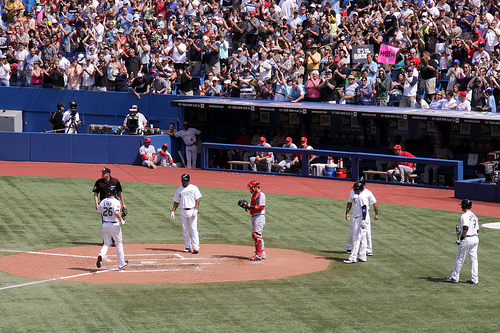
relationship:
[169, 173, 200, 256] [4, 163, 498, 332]
person on top of field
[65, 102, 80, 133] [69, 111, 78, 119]
man taking pictures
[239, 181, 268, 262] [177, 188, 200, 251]
player in uniform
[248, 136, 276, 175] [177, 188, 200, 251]
player in uniform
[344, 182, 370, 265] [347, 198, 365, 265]
player in uniform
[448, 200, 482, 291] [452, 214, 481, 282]
player in uniform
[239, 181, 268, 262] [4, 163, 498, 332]
catcher playing game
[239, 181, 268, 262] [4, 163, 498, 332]
umpire in game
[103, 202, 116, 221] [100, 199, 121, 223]
number on top of jersey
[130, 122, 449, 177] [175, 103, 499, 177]
team has dugout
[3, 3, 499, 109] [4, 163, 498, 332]
spectator at game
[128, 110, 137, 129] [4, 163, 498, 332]
camera at game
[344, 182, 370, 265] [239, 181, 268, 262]
player behind catcher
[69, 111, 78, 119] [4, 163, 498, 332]
picture of field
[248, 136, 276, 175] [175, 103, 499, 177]
player in bullpen